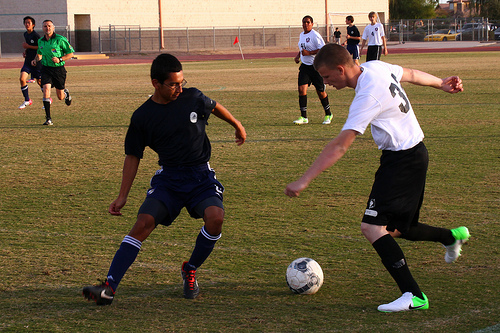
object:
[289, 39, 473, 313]
man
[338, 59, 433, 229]
black and white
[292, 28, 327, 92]
black and white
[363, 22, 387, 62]
black and white